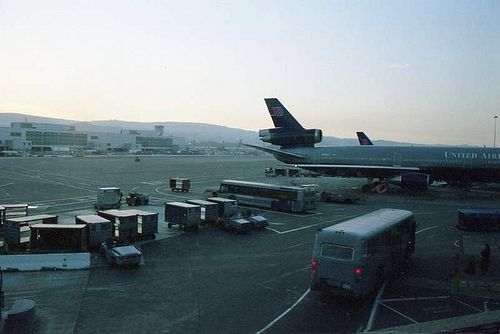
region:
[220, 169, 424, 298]
buses are on the tarmac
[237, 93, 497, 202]
a plane is at the terminal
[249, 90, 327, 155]
a jet engine is on the tail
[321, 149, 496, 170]
windows are along the fuselage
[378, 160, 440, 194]
jet engines are on each wing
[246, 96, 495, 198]
the plane is a passenger jet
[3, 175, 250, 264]
empty luggage carts are on the tarmac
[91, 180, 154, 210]
a service vehicle is pulling a luggage cart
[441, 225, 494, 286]
people are on the tarmas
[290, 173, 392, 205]
service vehicles are under the plane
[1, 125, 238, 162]
the hangers and buildings at the airport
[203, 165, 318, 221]
a bus parked near the plane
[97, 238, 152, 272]
a small car to pull containers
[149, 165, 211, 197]
a shipping container in the open lot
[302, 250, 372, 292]
the brake lights on the bus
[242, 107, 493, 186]
a plane parked at the airport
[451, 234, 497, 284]
people in the airport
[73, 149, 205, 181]
an empty space except one vehicle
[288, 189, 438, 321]
bus on the taramac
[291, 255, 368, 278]
tail lights of the bus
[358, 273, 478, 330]
lines on the tarmac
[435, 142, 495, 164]
writing on the plane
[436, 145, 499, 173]
owner's name on the plane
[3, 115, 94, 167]
building on the tarmac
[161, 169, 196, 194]
baggage cart on the tarmac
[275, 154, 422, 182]
wing of the plane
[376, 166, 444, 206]
engine on the plane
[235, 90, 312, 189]
tail of the plane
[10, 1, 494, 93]
An overcast sky.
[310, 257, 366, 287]
Round red taillights on back of bus.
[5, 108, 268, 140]
Mountains in the distance.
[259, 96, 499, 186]
A large parked airline.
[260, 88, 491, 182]
A huge United Airlines plane.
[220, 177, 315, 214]
A parked long bus.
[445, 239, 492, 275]
People waiting on the bus.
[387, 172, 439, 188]
The right engine of the airplane.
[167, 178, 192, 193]
An empty luggage carrier.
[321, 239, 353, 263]
Window on back of the bus.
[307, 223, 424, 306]
bus with back lights on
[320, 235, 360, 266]
back window of bus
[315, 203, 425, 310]
bus parked on runway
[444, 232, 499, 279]
people standing and waiting on runway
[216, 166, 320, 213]
bus with many windows on runway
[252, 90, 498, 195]
United Airlines plane on runway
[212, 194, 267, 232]
trucks on runway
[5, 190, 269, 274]
many containers on runway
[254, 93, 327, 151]
tail of airplane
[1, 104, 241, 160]
many buildings behind plane on runway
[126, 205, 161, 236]
tailor on parking lot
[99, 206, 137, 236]
tailor on parking lot